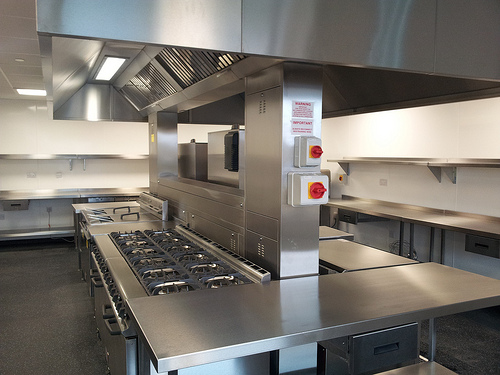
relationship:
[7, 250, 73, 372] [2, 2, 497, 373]
floor in kitchen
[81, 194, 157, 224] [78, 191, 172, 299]
handles on frying machine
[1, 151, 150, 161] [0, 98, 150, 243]
shelves on wall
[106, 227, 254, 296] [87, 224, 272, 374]
burners on stove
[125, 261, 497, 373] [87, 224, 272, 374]
steel table next to stove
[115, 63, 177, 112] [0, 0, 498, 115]
vent hanging from ceiling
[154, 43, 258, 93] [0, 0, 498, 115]
vent hanging from ceiling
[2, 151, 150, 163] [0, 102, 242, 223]
shelves hanging on white wall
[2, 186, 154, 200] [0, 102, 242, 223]
shelves hanging on white wall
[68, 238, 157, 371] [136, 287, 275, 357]
ovens underneath counter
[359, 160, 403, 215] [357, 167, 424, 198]
plug connected to wall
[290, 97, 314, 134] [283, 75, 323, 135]
warning label hanging on wall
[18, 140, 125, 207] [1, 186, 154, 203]
white wall standing behind shelves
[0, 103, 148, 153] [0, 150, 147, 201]
wall above counters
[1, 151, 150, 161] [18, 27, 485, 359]
shelves in kitchen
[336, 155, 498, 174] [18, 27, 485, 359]
shelves in kitchen